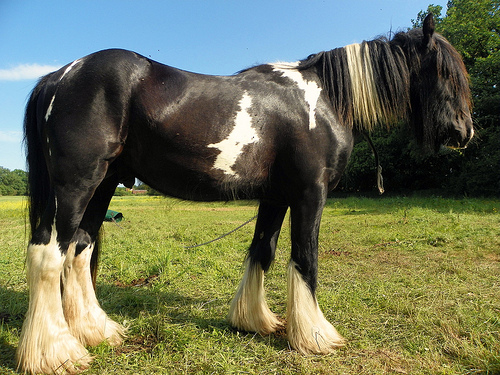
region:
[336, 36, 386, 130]
blonde mane of the horse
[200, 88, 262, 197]
white spot on the horse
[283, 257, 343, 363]
white leg of the horse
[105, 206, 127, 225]
bucket in the grass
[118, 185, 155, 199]
house in the background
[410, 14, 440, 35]
ear of the horse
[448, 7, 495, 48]
green trees in the background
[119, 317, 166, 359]
patch of brown grass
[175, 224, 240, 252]
tether for the horse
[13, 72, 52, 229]
black tail of the horse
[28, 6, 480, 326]
a black and white horse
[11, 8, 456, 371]
black and white horse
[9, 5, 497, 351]
a horse with long hair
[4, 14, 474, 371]
a black and white horse with long hair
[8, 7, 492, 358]
a horse in a field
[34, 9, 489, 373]
a horse standing in a field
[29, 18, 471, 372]
a horse standing on the grass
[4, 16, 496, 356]
a horse standing on green grass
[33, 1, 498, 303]
a horse that is black and white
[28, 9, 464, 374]
a long haired horse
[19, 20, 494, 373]
a horse with long feet hair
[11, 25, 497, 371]
a horse standing outside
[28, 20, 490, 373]
a horse standing on grass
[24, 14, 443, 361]
a horse standing in a field of green grass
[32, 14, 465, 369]
a horse standing in an area of grass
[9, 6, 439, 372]
a black and white horse outside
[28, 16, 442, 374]
a black and white horse standing on the grass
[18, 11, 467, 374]
a black and white horse in a field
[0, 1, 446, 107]
blue of daytime sky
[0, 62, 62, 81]
white cloud in sky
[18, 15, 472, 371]
side of standing pony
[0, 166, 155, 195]
line of trees on horizon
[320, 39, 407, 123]
black and white mane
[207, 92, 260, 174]
white patch on black coat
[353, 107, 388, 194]
rope hanging from neck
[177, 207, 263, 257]
rope suspended over grass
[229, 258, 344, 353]
long white hair on feet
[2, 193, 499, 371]
green grass on field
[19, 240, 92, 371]
hairy hoof of a horse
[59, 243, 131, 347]
hairy horse hoof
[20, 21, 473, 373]
a white and black horse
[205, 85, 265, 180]
whtie spot on a horse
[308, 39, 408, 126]
a horse's black and white mane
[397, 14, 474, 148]
head of a horse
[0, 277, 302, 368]
shadow of a horse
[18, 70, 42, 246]
a horse's tail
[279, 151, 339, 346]
leg of a horse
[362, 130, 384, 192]
a piece of rope